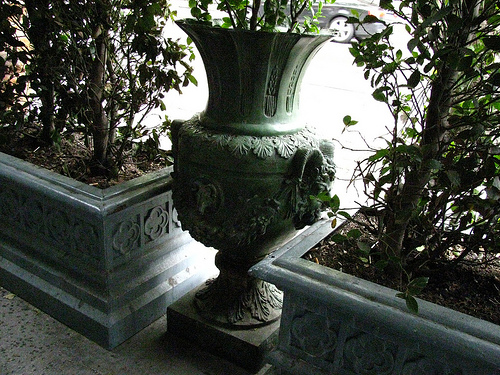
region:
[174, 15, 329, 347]
green stone vase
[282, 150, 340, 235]
design on side of stone vase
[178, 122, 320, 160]
design around edge of green stone vase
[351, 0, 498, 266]
small bush in stone planter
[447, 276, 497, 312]
dirt in stone planter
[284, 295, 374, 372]
design on side of stone planter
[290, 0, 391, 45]
black car driving on street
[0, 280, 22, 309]
small yellow leaf laying beside planter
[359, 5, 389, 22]
light on back of black car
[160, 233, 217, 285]
sun shining on side of stone planter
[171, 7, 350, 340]
a concrete vase shaped plantar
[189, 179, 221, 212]
a rams head on a plantar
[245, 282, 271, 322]
a leaf pattern on the base of a planter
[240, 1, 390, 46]
a parked black car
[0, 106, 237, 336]
a rectangular shaped planter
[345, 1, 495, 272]
a bush in a planter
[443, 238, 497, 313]
dirt in a planter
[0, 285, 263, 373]
the floor around planters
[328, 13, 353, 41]
a wheel on a car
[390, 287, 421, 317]
a green leaf hanging over a planter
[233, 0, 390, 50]
a parked car on the street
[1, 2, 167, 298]
a tree in a square pot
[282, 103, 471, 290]
the leaves are green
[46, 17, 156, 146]
the branches are brown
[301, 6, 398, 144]
the sun is bright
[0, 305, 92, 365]
the ground is dirty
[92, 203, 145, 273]
a clover shaped symbol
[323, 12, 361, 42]
the rim is white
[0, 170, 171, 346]
the flower pot is pastel green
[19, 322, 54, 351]
spots of green moss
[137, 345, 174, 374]
gray stone tile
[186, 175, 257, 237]
fancy carvings on the stone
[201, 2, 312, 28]
a small tree growing in a pot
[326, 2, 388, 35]
a black car parked nearby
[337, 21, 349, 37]
the chrome interior of the wheel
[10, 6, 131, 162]
small trees growing in a stone planter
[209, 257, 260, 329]
the ornate pedestal of a planter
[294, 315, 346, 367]
a stone flower carved on the planter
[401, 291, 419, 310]
dark green leaves on the tree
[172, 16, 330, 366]
green concrete pot for planting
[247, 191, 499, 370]
grey concrete planter with clover decal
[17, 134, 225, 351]
grey concrete planter with clover decal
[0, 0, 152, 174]
shrubbery in grey concrete planter with clover decal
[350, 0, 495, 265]
shrubber in grey concrete planter with clover decal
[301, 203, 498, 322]
potting soil in grey concrete planter with clover decal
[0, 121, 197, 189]
potting soil in grey concrete planter with clover decal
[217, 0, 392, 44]
black car in background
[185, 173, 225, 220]
a ram detail on green pot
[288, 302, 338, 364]
clover detail on grey pot